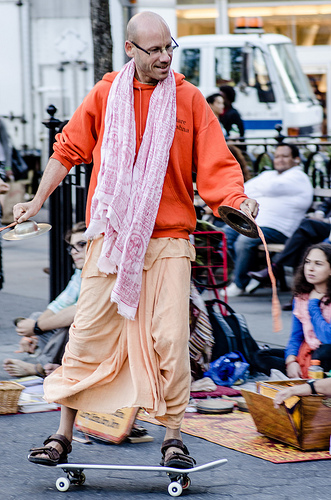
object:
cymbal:
[218, 206, 259, 239]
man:
[223, 143, 314, 297]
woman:
[255, 245, 330, 379]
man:
[2, 222, 87, 377]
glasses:
[66, 240, 87, 252]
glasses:
[127, 37, 179, 56]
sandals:
[29, 433, 72, 465]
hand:
[274, 380, 313, 408]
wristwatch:
[306, 379, 316, 394]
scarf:
[84, 60, 178, 322]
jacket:
[48, 66, 245, 237]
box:
[241, 379, 330, 452]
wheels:
[167, 482, 182, 497]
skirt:
[43, 237, 196, 428]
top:
[244, 169, 313, 237]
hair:
[295, 243, 330, 292]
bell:
[2, 219, 52, 241]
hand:
[309, 290, 324, 299]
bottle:
[307, 359, 323, 378]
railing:
[40, 104, 94, 305]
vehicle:
[172, 33, 323, 157]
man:
[14, 12, 260, 464]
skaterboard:
[28, 455, 230, 499]